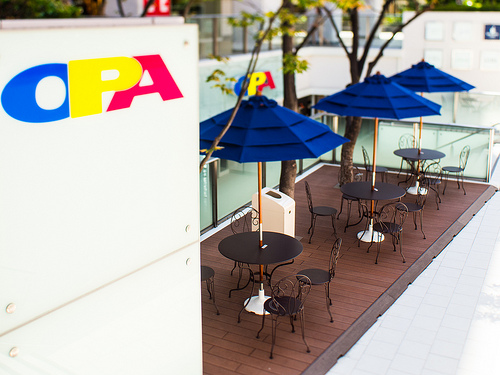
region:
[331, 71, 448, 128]
blue umbrella on deck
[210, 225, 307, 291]
small brown table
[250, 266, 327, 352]
brown chair around the table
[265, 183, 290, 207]
small opening on white trash can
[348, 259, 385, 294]
red wood on floor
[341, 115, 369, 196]
tree on the deck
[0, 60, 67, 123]
blue round large font letter O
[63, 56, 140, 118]
large yellow bolded letter "P"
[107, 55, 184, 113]
slightly obscured bolded red letter 'A'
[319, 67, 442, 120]
blue canvas umbrella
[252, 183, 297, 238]
white metal trash receptacle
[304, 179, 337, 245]
metal brown wire chair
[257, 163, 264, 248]
brown wooden parasol handle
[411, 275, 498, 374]
white ceramic tile flooring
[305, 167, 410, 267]
outdoor table and chair set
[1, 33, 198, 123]
colorized logo on white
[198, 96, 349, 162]
a dark blue patio umbrella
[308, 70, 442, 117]
a dark blue patio umbrella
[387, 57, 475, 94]
a dark blue patio umbrella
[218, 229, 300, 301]
a black patio table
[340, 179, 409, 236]
a black patio table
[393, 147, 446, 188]
a black patio table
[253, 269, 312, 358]
a black patio chair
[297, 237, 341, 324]
a black patio chair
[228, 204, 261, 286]
a black patio chair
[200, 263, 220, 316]
a black patio chair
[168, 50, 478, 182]
umbrellas over the chairs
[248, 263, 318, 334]
chair next to table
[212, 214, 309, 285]
table next to chair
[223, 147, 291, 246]
pole under the umbrella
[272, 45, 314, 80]
leaves on the tree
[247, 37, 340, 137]
branch of the tree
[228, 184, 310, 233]
trash can next to tables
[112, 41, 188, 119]
red letter on side of building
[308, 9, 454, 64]
branches of the tree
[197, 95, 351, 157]
A blue umbrella.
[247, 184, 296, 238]
A white box.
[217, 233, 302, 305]
A round black table.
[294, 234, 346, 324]
A chair near a table.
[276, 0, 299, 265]
A brown tree trunk.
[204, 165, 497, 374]
A paved sitting area.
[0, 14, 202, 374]
A large white sign.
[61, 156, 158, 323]
white wall with lines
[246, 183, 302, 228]
white trash can on floor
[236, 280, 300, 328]
white base on umbrella stand